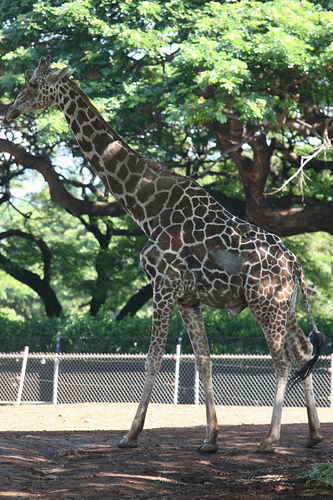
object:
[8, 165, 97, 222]
sunshine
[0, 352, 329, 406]
enclosure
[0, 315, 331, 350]
bushes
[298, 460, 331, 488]
grass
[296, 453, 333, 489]
patch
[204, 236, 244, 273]
gray spot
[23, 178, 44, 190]
sky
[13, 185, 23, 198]
light blue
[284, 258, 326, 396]
tail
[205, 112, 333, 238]
branch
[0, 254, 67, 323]
trunk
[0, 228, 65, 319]
tree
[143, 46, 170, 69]
ground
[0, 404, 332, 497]
dirt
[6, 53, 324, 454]
giraffe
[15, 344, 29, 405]
pole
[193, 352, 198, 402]
pole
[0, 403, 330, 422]
gravel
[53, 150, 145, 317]
tree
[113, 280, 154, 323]
tree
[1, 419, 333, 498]
shade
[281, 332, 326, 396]
hair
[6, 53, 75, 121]
head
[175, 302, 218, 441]
leg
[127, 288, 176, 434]
leg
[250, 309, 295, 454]
leg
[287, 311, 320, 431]
leg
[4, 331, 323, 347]
wire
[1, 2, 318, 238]
tree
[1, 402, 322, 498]
ground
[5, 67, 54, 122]
face